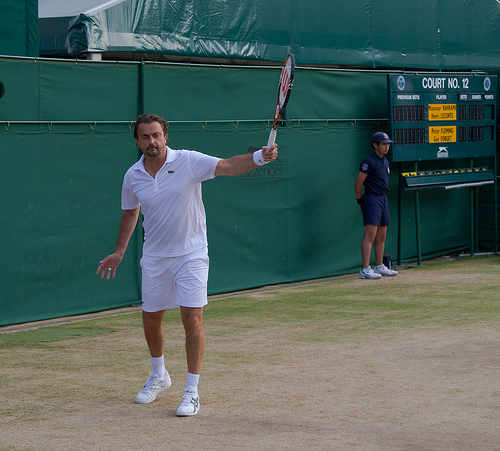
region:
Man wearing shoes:
[134, 369, 213, 416]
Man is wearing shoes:
[134, 367, 201, 415]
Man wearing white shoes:
[132, 368, 204, 418]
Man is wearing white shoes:
[132, 366, 201, 418]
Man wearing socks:
[147, 347, 201, 397]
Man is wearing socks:
[146, 346, 202, 396]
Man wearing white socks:
[146, 352, 201, 390]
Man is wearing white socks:
[147, 352, 203, 389]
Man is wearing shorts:
[136, 240, 213, 315]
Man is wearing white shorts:
[140, 241, 213, 316]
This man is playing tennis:
[72, 53, 321, 415]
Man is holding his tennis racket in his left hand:
[249, 48, 309, 191]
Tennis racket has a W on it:
[268, 47, 305, 118]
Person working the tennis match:
[346, 113, 413, 293]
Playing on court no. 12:
[419, 65, 474, 93]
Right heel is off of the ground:
[158, 363, 174, 398]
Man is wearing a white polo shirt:
[103, 135, 248, 265]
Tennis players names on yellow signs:
[425, 94, 463, 148]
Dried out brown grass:
[237, 310, 487, 448]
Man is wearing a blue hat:
[359, 120, 399, 157]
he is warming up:
[63, 35, 379, 430]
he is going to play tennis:
[82, 20, 360, 447]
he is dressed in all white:
[82, 42, 330, 423]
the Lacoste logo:
[163, 164, 181, 184]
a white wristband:
[246, 133, 282, 178]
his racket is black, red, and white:
[258, 19, 308, 162]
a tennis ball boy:
[346, 107, 403, 292]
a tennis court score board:
[369, 53, 499, 172]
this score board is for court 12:
[374, 51, 499, 292]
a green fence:
[3, 46, 495, 297]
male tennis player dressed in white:
[86, 51, 340, 428]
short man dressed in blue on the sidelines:
[349, 128, 411, 284]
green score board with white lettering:
[389, 72, 496, 167]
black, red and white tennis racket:
[254, 47, 312, 170]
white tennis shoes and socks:
[136, 366, 206, 419]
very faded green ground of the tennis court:
[362, 292, 494, 432]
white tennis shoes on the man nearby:
[359, 266, 403, 278]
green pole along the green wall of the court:
[9, 112, 131, 141]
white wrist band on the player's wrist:
[251, 147, 267, 168]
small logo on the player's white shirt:
[165, 166, 176, 176]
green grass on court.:
[333, 300, 372, 307]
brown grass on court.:
[340, 404, 395, 429]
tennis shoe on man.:
[174, 398, 200, 425]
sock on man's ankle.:
[185, 373, 200, 389]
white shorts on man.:
[184, 270, 202, 296]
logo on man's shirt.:
[165, 165, 177, 176]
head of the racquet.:
[275, 64, 294, 102]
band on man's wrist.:
[252, 150, 264, 164]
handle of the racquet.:
[265, 130, 275, 143]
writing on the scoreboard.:
[415, 78, 465, 90]